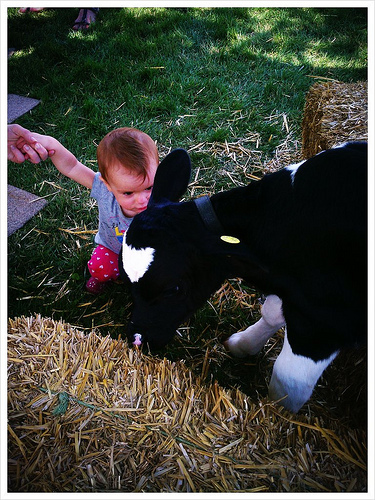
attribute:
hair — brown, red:
[93, 126, 158, 185]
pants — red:
[84, 242, 126, 289]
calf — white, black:
[115, 144, 367, 371]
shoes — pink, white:
[81, 239, 137, 291]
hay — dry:
[111, 390, 206, 422]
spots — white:
[121, 233, 150, 282]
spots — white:
[285, 163, 303, 174]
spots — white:
[330, 143, 346, 148]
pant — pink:
[86, 242, 121, 284]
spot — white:
[116, 226, 167, 290]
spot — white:
[124, 237, 147, 278]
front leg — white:
[255, 325, 344, 413]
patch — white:
[118, 235, 163, 285]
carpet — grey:
[8, 181, 49, 239]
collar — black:
[191, 193, 233, 256]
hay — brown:
[43, 342, 307, 495]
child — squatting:
[17, 125, 158, 289]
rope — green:
[24, 372, 236, 470]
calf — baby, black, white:
[119, 135, 368, 417]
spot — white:
[282, 154, 311, 182]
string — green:
[29, 381, 243, 466]